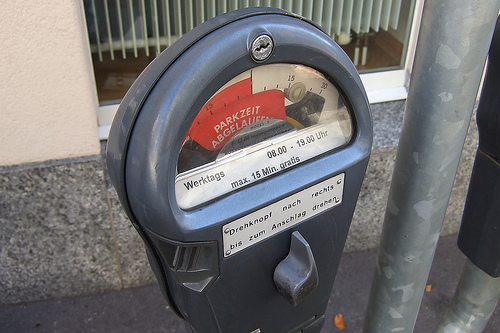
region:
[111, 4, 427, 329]
a parking meter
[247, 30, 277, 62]
key hole in the top of the meter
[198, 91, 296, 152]
white writing on a red background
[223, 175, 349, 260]
black writing on a white background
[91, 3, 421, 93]
blinds on the window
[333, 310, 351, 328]
small leaf on the ground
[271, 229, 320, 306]
knob on the parking meter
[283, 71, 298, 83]
black number on a white background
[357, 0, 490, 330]
silver pole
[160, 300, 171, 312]
white speck on the ground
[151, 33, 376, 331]
the parking metter is grey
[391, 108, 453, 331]
the post is metal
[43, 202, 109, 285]
the wall is grey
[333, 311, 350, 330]
the leaf is brown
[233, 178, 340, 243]
letters are on the meter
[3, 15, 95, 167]
the wall is tan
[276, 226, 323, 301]
the knob is faacing up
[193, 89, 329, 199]
the letters are in german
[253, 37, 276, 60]
the lock is silver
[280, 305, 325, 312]
Sukver and black parking meter.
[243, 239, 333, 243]
Sukver and black parking meter.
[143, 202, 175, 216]
Sukver and black parking meter.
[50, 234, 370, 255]
Sukver and black parking meter.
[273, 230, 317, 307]
the turn handle on the parking meter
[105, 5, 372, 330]
the parking meter on the sidewalk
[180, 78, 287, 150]
the red area on the parking meter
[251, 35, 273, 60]
the lock on the parking meter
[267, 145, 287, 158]
the 08.00 on the parking meter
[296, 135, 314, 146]
the 19.00 on the parking meter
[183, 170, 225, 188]
the word "Werktags" on the meter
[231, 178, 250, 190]
the word "max." on the parking meter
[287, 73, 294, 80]
the 15 on the parking meter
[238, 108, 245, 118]
the "Z" on the parking meter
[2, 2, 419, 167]
tan wall by side of window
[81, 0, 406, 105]
white vertical blinds covering window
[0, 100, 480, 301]
black and grey stone base of building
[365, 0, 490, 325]
gray pole covered with lighter grey shapes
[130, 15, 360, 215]
arched glass window on parking meter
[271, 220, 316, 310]
worn curved knob for feeding coins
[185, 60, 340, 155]
red and white panels with lines for time remaining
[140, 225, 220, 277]
slanted coin slots on side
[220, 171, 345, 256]
metal strip with black print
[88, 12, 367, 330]
gray metal parking meter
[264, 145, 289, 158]
black numbers on meter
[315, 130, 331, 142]
black letters on meter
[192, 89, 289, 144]
red label on meter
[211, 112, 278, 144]
white letters on red label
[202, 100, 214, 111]
black numbers on red label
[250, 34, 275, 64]
silver keyhole on meter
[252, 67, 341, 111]
white label on meter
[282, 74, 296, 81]
black numbers on white label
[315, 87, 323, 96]
black line on white label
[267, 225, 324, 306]
turn knob on the parking meter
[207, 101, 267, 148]
white lettering on red background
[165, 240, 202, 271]
coin slot on the parking meter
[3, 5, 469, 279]
building behind the parking meter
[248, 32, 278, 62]
keyhole on the parking meter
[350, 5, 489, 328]
silver pole next to parking meter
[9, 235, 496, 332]
sidewalk the parking meter is on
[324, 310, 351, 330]
leaf on the sidewalk